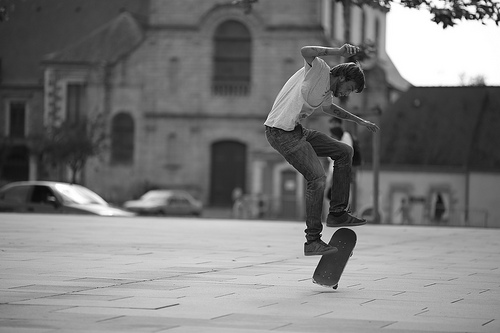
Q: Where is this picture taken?
A: Across from a church.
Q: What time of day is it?
A: Afternoon.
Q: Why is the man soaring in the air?
A: He is jumping above his skateboard.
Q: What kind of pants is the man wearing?
A: Jeans.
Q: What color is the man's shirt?
A: White.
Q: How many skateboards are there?
A: One.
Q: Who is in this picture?
A: A man.